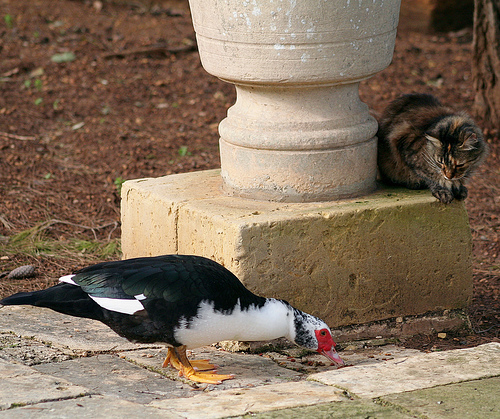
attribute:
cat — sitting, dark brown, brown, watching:
[378, 93, 484, 208]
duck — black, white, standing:
[0, 255, 344, 388]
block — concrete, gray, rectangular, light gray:
[119, 169, 473, 353]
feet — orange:
[161, 343, 233, 387]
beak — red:
[325, 347, 342, 367]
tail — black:
[2, 285, 75, 314]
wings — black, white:
[65, 264, 177, 299]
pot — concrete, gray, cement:
[186, 1, 403, 201]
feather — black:
[164, 281, 192, 302]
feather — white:
[238, 315, 262, 328]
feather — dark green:
[83, 285, 123, 298]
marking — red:
[317, 327, 334, 350]